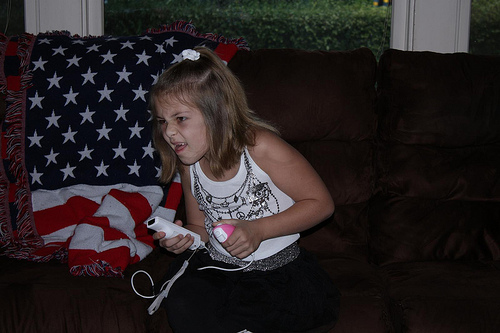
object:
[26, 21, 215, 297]
flag throw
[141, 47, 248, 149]
hair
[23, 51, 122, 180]
stars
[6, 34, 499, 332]
couch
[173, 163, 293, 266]
tank top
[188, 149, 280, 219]
necklaces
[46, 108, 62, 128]
star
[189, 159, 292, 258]
top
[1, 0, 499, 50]
window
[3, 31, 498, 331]
sofa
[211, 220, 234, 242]
controller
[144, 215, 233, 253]
game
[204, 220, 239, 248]
pink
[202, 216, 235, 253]
wii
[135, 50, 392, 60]
window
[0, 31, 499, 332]
background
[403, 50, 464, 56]
frame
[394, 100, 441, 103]
window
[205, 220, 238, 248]
will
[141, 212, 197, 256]
will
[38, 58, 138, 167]
usa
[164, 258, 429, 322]
black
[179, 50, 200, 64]
band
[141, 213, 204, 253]
remote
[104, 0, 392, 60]
leaves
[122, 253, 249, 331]
wire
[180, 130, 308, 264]
shirt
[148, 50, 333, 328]
girl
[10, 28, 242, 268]
flag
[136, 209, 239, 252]
remote control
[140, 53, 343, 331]
hair holder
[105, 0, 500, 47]
hedges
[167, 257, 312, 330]
pant